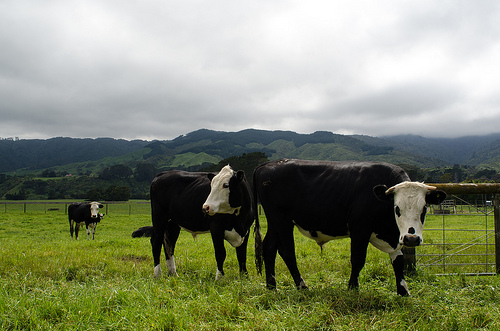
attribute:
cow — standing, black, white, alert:
[67, 199, 102, 240]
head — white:
[88, 200, 104, 220]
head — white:
[200, 164, 244, 216]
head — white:
[383, 178, 439, 245]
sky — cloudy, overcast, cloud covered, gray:
[2, 1, 499, 139]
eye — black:
[221, 183, 232, 189]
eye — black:
[394, 207, 400, 217]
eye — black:
[422, 206, 426, 218]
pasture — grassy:
[3, 192, 499, 331]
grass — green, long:
[3, 214, 499, 331]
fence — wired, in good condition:
[1, 200, 495, 218]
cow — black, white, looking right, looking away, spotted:
[143, 161, 255, 287]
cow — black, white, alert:
[251, 157, 450, 296]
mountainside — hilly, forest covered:
[2, 127, 500, 198]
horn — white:
[425, 183, 439, 193]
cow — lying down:
[128, 225, 158, 240]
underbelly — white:
[294, 224, 398, 253]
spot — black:
[407, 223, 418, 235]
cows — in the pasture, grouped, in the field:
[65, 157, 446, 300]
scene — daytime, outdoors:
[1, 2, 498, 330]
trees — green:
[106, 162, 136, 179]